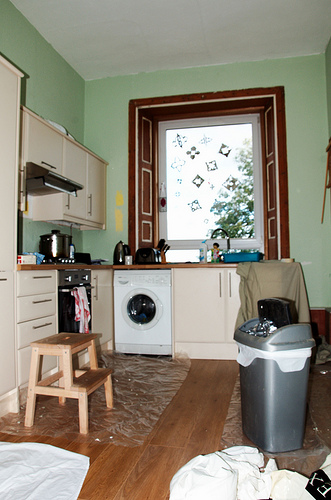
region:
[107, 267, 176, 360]
front of white washing machine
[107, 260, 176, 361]
washing machine under kitchen counter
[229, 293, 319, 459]
open gray trash can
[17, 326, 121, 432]
wooden step stool near counter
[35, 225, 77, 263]
silver slow cooker on counter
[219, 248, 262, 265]
blue plastic utility bin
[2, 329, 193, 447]
piece of clear plastic on floor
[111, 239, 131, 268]
clothing iron on coutertop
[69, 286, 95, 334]
red and white towel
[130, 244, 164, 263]
toaster on counter top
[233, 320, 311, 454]
Trash can filled with garbage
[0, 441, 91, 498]
White dropcloth on the floor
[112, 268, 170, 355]
Built-in dryer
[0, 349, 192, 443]
Sheet of plastic on the floor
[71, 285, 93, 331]
Towel hanging from the oven handle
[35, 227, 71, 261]
Pot on the stove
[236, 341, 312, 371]
White plastic bag lining the garbge pail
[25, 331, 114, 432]
Wooden step stool in front of the cabinets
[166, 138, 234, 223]
Stickers on the window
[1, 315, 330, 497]
Wooden flooring protected with plastic and sheets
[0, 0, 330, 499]
Green walled kitchen being remodeled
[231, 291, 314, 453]
Gray trashcan with white bag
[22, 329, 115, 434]
Light brown wood step stool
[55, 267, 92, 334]
Silver and black oven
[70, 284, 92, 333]
Red and white towel hanging from an oven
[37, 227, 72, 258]
Large metal pot with lid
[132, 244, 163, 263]
Silver toaster on the counter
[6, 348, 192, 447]
Plastic covering the floor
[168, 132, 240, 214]
Decals on a window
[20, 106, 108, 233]
White cabinets with metal handles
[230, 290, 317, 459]
A gray trash can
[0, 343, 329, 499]
The floor is made of hardwood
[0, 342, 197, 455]
Plastic is on the floor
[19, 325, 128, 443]
A wooden step stool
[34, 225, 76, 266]
A silver pot in the background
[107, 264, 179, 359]
A white colored dishwasher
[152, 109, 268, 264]
A window with a white frame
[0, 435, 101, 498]
White cloth on the floor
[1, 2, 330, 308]
The walls are mint green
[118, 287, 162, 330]
The dishwasher is circular shaped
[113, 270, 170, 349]
the laundry machine is white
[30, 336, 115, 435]
the step stool is made of wood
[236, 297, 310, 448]
the garbage is full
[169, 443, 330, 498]
trash on the floor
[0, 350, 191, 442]
plastic on the floor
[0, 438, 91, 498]
blanket on the floor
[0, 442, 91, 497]
the blanket is white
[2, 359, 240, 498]
the floor is made of wood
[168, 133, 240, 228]
the window has stickers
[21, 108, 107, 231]
the cabinets are beige